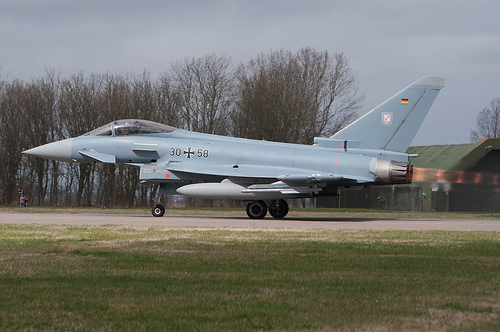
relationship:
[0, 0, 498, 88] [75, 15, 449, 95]
clouds in sky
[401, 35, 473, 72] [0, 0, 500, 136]
white clouds in sky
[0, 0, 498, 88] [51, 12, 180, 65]
clouds in sky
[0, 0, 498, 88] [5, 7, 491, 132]
clouds in sky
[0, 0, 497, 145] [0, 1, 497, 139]
clouds in sky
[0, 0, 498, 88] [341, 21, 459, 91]
clouds in sky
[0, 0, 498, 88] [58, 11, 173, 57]
clouds in sky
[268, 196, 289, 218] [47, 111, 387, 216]
tire on plane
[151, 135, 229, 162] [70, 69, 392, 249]
sign on plane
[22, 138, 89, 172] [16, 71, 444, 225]
nose on plane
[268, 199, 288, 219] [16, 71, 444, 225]
wheel on plane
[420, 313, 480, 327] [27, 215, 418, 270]
spot on grass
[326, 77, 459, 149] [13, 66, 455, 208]
tail of plane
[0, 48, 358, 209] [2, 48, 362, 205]
branches on tree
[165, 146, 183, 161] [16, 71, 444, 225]
number on plane